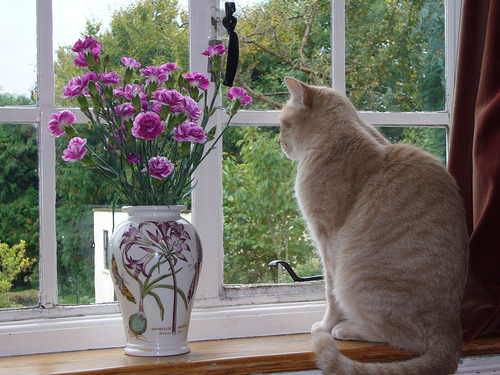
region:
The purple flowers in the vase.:
[49, 38, 249, 177]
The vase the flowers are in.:
[104, 205, 199, 358]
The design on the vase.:
[118, 225, 193, 340]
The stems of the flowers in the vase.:
[90, 98, 220, 199]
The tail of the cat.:
[303, 330, 453, 374]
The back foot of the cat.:
[330, 312, 369, 337]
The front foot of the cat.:
[312, 318, 329, 331]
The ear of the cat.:
[286, 76, 311, 105]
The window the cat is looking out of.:
[1, 0, 451, 311]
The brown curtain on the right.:
[450, 0, 492, 339]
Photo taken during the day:
[6, 7, 494, 367]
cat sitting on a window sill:
[257, 71, 477, 356]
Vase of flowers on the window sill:
[66, 50, 212, 352]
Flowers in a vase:
[29, 46, 243, 231]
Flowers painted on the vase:
[105, 205, 203, 354]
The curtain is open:
[454, 0, 492, 347]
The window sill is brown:
[37, 330, 488, 363]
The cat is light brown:
[265, 66, 474, 353]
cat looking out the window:
[262, 75, 474, 350]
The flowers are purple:
[60, 30, 228, 177]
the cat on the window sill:
[254, 64, 469, 374]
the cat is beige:
[245, 51, 470, 370]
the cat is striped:
[261, 66, 471, 372]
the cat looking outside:
[277, 71, 479, 372]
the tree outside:
[232, 18, 332, 93]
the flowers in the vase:
[49, 27, 219, 196]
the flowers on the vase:
[122, 226, 203, 295]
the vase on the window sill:
[106, 200, 211, 360]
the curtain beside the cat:
[450, 5, 498, 332]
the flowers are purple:
[52, 36, 222, 176]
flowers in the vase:
[56, 38, 209, 185]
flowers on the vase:
[123, 230, 196, 293]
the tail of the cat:
[302, 325, 452, 373]